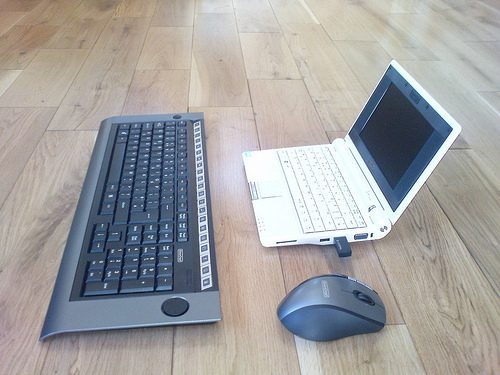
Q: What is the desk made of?
A: Wood.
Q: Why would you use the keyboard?
A: To type.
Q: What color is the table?
A: Brown.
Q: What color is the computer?
A: White.